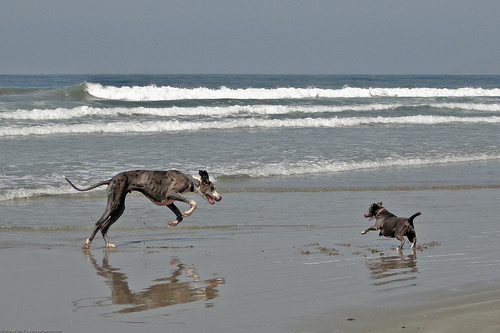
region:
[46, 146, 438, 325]
two dogs are on the beach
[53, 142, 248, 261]
the bigger dog is on the left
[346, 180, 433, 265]
the smaller dog is on the right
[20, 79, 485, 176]
the ocean can be seen in the background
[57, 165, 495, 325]
the dogs are on the beach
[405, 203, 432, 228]
the smaller dogs tail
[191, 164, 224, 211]
the bigger dogs head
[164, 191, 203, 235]
the bigger dogs front feet are off of the ground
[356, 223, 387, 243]
the smaller dogs feet are off of the ground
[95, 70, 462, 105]
the ocean has waves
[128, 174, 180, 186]
A dog running on low water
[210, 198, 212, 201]
The mouth is open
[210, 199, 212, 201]
The inside of the mouth red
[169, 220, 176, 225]
The paw is in the air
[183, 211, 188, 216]
The paw is folded back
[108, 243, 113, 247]
Rear paw in the water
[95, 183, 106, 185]
A long tail sticking out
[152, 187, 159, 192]
Ribs are protruding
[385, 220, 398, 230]
A small dog in the water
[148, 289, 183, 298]
Shadow of big dog in water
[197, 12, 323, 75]
blue sky above the water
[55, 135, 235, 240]
dog on the beach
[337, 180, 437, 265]
little dog on the beach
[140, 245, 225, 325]
reflection on the ground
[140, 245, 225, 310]
reflection of the dog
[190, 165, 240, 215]
head of the dog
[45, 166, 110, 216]
tail of the dog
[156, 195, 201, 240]
front paws of the dog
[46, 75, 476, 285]
two dogs on beach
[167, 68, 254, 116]
white water in the ocean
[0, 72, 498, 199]
the large body of water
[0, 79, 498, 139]
the small waves in the ocean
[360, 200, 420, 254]
the small dog on the wet sand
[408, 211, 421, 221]
the tail on the small dog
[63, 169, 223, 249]
the large dog on the wet sand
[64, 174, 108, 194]
the tail on the large dog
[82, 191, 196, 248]
the legs on the large dog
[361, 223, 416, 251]
the legs on the small dog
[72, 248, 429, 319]
the reflection of the dogs on the sand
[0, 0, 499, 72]
the sky above the ocean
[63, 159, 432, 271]
Two dogs on a beach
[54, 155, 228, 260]
Grey hound dog on the beach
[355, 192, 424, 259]
Territor dog on the beach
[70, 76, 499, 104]
Waves on the water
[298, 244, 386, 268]
Paw prints on the beach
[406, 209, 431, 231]
Stubbie tail on the territor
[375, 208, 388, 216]
Collar on the territor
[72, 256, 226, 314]
Dog shadow on the beach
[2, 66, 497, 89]
Blue ocean in the distance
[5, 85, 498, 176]
Waves breaking against the beach